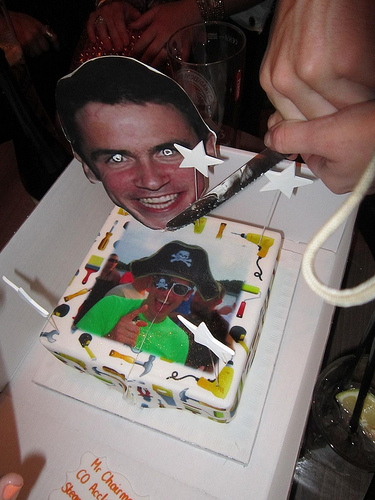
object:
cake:
[38, 203, 281, 423]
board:
[268, 174, 352, 254]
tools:
[231, 229, 275, 347]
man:
[75, 273, 192, 365]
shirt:
[76, 295, 189, 367]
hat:
[130, 240, 219, 303]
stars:
[174, 139, 314, 199]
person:
[256, 0, 374, 227]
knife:
[165, 148, 286, 230]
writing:
[58, 451, 130, 500]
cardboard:
[55, 55, 218, 230]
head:
[52, 56, 219, 232]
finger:
[0, 471, 23, 499]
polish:
[6, 482, 18, 495]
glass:
[170, 43, 250, 131]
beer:
[208, 80, 237, 128]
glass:
[293, 355, 375, 500]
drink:
[311, 387, 374, 499]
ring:
[45, 31, 55, 40]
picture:
[39, 204, 283, 424]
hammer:
[108, 349, 156, 378]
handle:
[108, 349, 135, 367]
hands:
[259, 77, 375, 195]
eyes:
[108, 148, 176, 163]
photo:
[74, 220, 250, 375]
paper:
[32, 370, 77, 399]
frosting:
[202, 165, 253, 201]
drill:
[166, 349, 244, 399]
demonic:
[168, 247, 194, 267]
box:
[0, 142, 361, 498]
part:
[146, 14, 178, 32]